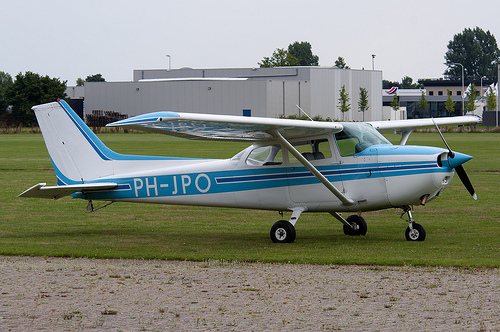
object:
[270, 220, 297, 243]
wheel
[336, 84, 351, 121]
trees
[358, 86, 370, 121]
trees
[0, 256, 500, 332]
dirt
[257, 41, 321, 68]
tree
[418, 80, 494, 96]
building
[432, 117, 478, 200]
propeller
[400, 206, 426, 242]
landing gear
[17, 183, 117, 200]
wing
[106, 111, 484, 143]
wing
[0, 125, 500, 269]
grass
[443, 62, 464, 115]
light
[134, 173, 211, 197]
white letters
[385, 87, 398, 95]
flag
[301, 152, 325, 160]
seats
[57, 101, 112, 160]
stripe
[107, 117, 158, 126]
stripe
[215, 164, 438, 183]
stripe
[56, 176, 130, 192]
stripe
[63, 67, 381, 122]
building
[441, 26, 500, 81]
leaves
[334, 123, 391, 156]
windshield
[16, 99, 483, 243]
airplane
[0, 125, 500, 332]
ground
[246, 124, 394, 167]
cockpit